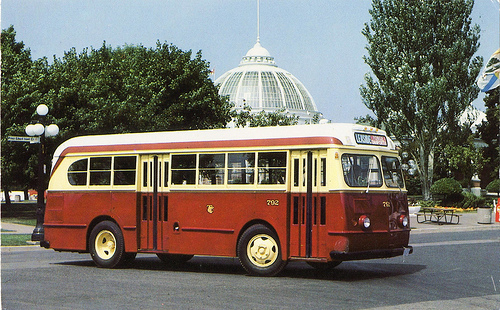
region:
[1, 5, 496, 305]
A street scene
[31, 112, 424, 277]
A bus is parked on the street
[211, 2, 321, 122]
A building dome is in the background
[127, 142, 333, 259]
The bus has two doors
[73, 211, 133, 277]
The bus's rear tire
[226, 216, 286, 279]
The bus's front tire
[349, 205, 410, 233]
These are headlights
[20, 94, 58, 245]
A lamp post is behind the bus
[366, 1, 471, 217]
A tree is growing here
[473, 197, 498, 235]
A garbage can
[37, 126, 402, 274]
bus on black road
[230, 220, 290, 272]
tire on side of bus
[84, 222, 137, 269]
tire on side of bus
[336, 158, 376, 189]
window on front of bus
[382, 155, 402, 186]
window on front of bus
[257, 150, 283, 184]
window on side of bus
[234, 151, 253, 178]
window on side of bus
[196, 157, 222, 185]
window on side of bus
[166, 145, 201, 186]
window on side of bus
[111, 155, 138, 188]
window on side of bus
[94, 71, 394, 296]
a bus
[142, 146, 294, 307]
a bus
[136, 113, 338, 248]
a bus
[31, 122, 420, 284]
a bus on the street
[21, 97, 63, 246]
lamp with many lights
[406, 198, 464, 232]
an outdoor picnic table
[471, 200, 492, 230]
a cement trash bin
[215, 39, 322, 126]
white building with a circular top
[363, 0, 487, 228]
tall tree behind table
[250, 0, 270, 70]
rod emerging from atop building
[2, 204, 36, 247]
paved walkway amid grass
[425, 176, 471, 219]
round bush behind table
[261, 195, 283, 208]
yellow number on side of bus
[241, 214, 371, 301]
a bus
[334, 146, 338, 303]
a bus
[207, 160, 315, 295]
a bus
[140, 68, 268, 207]
a bus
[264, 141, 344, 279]
a bus